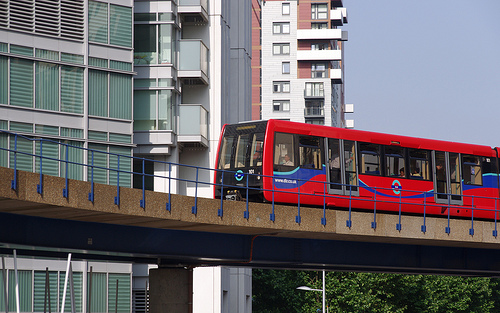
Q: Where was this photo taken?
A: Near a tram-rail.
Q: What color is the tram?
A: Red.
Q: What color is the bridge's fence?
A: Blue.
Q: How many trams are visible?
A: One.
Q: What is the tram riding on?
A: A bridge.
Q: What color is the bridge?
A: Brown.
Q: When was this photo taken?
A: Outside, during the daytime.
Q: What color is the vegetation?
A: Green.